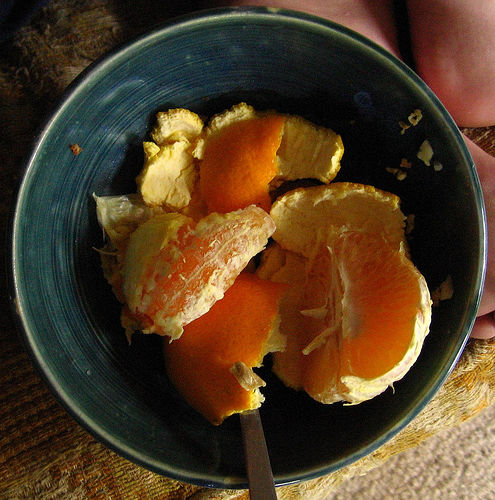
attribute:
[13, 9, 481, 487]
bowl — green, ceramic, blue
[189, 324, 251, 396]
peel — orange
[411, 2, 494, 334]
person — white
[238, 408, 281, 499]
utensil — silver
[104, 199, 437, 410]
orange — broken, peeled, slices, small, pieces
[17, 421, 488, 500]
couch — brown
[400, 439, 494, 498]
surface — white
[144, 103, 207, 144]
peal — tiny